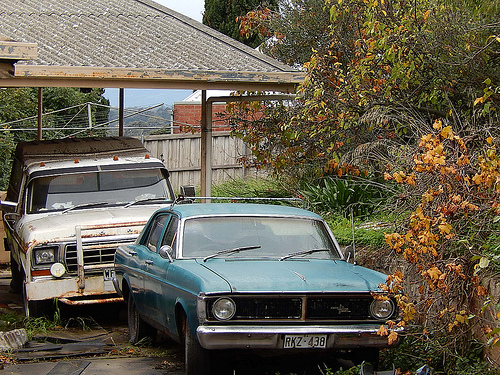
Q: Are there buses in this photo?
A: No, there are no buses.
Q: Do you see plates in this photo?
A: Yes, there is a plate.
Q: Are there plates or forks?
A: Yes, there is a plate.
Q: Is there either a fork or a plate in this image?
A: Yes, there is a plate.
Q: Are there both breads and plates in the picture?
A: No, there is a plate but no breads.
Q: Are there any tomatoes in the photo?
A: No, there are no tomatoes.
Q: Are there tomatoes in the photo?
A: No, there are no tomatoes.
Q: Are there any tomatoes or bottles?
A: No, there are no tomatoes or bottles.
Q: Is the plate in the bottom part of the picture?
A: Yes, the plate is in the bottom of the image.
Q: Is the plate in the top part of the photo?
A: No, the plate is in the bottom of the image.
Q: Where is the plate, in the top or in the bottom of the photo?
A: The plate is in the bottom of the image.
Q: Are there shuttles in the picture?
A: No, there are no shuttles.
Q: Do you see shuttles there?
A: No, there are no shuttles.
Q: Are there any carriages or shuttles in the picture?
A: No, there are no shuttles or carriages.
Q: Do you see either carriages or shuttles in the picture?
A: No, there are no shuttles or carriages.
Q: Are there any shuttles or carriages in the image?
A: No, there are no shuttles or carriages.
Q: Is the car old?
A: Yes, the car is old.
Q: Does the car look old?
A: Yes, the car is old.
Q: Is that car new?
A: No, the car is old.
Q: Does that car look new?
A: No, the car is old.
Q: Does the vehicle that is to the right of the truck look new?
A: No, the car is old.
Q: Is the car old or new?
A: The car is old.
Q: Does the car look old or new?
A: The car is old.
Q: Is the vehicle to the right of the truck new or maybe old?
A: The car is old.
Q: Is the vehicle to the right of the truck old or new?
A: The car is old.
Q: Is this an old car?
A: Yes, this is an old car.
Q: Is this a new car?
A: No, this is an old car.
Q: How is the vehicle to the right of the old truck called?
A: The vehicle is a car.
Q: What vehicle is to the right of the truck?
A: The vehicle is a car.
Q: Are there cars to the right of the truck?
A: Yes, there is a car to the right of the truck.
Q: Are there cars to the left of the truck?
A: No, the car is to the right of the truck.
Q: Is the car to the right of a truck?
A: Yes, the car is to the right of a truck.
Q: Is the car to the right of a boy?
A: No, the car is to the right of a truck.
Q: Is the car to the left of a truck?
A: No, the car is to the right of a truck.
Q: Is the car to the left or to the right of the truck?
A: The car is to the right of the truck.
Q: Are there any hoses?
A: No, there are no hoses.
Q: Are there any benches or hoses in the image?
A: No, there are no hoses or benches.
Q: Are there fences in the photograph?
A: Yes, there is a fence.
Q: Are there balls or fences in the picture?
A: Yes, there is a fence.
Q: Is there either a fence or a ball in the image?
A: Yes, there is a fence.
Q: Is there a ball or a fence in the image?
A: Yes, there is a fence.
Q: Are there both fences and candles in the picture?
A: No, there is a fence but no candles.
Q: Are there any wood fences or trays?
A: Yes, there is a wood fence.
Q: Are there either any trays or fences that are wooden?
A: Yes, the fence is wooden.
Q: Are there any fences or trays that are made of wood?
A: Yes, the fence is made of wood.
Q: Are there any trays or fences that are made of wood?
A: Yes, the fence is made of wood.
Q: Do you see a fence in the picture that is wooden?
A: Yes, there is a wood fence.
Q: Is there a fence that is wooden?
A: Yes, there is a fence that is wooden.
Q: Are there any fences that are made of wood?
A: Yes, there is a fence that is made of wood.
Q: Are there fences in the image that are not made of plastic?
A: Yes, there is a fence that is made of wood.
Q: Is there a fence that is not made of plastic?
A: Yes, there is a fence that is made of wood.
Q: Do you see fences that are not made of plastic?
A: Yes, there is a fence that is made of wood.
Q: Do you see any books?
A: No, there are no books.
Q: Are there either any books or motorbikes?
A: No, there are no books or motorbikes.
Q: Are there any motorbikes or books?
A: No, there are no books or motorbikes.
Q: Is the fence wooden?
A: Yes, the fence is wooden.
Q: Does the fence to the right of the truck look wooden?
A: Yes, the fence is wooden.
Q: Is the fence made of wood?
A: Yes, the fence is made of wood.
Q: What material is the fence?
A: The fence is made of wood.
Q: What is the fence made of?
A: The fence is made of wood.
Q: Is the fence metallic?
A: No, the fence is wooden.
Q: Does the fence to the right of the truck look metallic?
A: No, the fence is wooden.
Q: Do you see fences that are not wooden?
A: No, there is a fence but it is wooden.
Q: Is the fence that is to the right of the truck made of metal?
A: No, the fence is made of wood.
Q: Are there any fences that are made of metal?
A: No, there is a fence but it is made of wood.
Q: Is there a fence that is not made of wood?
A: No, there is a fence but it is made of wood.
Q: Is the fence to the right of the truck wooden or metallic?
A: The fence is wooden.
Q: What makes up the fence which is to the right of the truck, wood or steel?
A: The fence is made of wood.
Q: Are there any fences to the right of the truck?
A: Yes, there is a fence to the right of the truck.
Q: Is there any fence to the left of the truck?
A: No, the fence is to the right of the truck.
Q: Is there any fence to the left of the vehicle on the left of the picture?
A: No, the fence is to the right of the truck.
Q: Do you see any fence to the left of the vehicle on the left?
A: No, the fence is to the right of the truck.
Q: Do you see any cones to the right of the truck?
A: No, there is a fence to the right of the truck.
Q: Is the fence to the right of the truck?
A: Yes, the fence is to the right of the truck.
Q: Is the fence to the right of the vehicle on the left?
A: Yes, the fence is to the right of the truck.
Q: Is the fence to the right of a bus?
A: No, the fence is to the right of the truck.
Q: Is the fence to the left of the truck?
A: No, the fence is to the right of the truck.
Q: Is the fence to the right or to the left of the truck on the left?
A: The fence is to the right of the truck.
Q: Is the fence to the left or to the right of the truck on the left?
A: The fence is to the right of the truck.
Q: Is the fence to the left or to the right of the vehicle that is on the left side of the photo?
A: The fence is to the right of the truck.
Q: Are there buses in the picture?
A: No, there are no buses.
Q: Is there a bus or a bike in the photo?
A: No, there are no buses or bikes.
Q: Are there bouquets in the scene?
A: No, there are no bouquets.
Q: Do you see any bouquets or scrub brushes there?
A: No, there are no bouquets or scrub brushes.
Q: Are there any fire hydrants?
A: No, there are no fire hydrants.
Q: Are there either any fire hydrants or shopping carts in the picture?
A: No, there are no fire hydrants or shopping carts.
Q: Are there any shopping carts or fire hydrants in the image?
A: No, there are no fire hydrants or shopping carts.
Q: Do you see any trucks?
A: Yes, there is a truck.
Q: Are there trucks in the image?
A: Yes, there is a truck.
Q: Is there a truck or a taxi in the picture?
A: Yes, there is a truck.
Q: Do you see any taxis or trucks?
A: Yes, there is a truck.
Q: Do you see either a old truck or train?
A: Yes, there is an old truck.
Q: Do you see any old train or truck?
A: Yes, there is an old truck.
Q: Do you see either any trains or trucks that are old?
A: Yes, the truck is old.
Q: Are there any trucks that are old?
A: Yes, there is an old truck.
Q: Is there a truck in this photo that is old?
A: Yes, there is a truck that is old.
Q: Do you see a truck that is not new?
A: Yes, there is a old truck.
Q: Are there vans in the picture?
A: No, there are no vans.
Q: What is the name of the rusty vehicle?
A: The vehicle is a truck.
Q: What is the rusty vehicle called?
A: The vehicle is a truck.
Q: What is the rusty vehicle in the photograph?
A: The vehicle is a truck.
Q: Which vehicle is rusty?
A: The vehicle is a truck.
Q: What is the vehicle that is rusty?
A: The vehicle is a truck.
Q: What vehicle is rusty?
A: The vehicle is a truck.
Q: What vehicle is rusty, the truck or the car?
A: The truck is rusty.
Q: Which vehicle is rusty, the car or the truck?
A: The truck is rusty.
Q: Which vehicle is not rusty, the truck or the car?
A: The car is not rusty.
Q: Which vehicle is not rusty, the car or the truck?
A: The car is not rusty.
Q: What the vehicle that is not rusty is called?
A: The vehicle is a car.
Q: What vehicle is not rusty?
A: The vehicle is a car.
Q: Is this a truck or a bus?
A: This is a truck.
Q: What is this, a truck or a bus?
A: This is a truck.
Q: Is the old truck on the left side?
A: Yes, the truck is on the left of the image.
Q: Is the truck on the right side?
A: No, the truck is on the left of the image.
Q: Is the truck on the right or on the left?
A: The truck is on the left of the image.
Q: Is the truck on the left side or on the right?
A: The truck is on the left of the image.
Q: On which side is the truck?
A: The truck is on the left of the image.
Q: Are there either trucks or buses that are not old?
A: No, there is a truck but it is old.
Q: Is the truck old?
A: Yes, the truck is old.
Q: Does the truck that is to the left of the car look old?
A: Yes, the truck is old.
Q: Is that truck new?
A: No, the truck is old.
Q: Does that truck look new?
A: No, the truck is old.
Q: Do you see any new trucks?
A: No, there is a truck but it is old.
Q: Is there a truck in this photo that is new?
A: No, there is a truck but it is old.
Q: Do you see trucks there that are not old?
A: No, there is a truck but it is old.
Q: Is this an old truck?
A: Yes, this is an old truck.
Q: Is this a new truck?
A: No, this is an old truck.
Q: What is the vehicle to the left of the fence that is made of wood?
A: The vehicle is a truck.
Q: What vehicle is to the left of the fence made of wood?
A: The vehicle is a truck.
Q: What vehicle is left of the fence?
A: The vehicle is a truck.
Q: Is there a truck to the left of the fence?
A: Yes, there is a truck to the left of the fence.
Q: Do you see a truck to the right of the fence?
A: No, the truck is to the left of the fence.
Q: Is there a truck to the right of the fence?
A: No, the truck is to the left of the fence.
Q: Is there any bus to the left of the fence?
A: No, there is a truck to the left of the fence.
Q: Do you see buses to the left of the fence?
A: No, there is a truck to the left of the fence.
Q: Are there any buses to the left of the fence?
A: No, there is a truck to the left of the fence.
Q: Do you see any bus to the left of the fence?
A: No, there is a truck to the left of the fence.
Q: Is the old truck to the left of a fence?
A: Yes, the truck is to the left of a fence.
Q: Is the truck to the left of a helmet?
A: No, the truck is to the left of a fence.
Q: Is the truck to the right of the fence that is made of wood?
A: No, the truck is to the left of the fence.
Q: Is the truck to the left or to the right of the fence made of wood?
A: The truck is to the left of the fence.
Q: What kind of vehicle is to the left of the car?
A: The vehicle is a truck.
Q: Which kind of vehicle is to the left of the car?
A: The vehicle is a truck.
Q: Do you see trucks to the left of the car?
A: Yes, there is a truck to the left of the car.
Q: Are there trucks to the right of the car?
A: No, the truck is to the left of the car.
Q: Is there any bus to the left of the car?
A: No, there is a truck to the left of the car.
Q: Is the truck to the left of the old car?
A: Yes, the truck is to the left of the car.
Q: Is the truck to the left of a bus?
A: No, the truck is to the left of the car.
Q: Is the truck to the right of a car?
A: No, the truck is to the left of a car.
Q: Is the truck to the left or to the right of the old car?
A: The truck is to the left of the car.